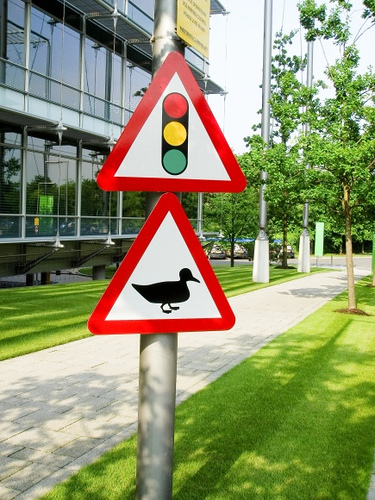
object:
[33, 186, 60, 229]
reflection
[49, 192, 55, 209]
grass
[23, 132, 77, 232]
window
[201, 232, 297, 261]
cars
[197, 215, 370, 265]
lot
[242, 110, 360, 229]
tree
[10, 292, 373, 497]
shadows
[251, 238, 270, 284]
cement base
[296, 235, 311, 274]
cement base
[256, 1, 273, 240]
light post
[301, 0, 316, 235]
light post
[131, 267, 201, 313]
silhouette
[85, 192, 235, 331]
triangle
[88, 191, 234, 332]
sign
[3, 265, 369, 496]
sidewalk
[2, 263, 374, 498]
lawn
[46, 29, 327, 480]
signs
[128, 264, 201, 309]
duck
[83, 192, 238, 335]
duck sign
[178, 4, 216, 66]
sign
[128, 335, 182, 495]
pole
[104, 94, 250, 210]
sign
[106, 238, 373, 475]
ground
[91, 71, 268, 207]
sign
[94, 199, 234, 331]
sign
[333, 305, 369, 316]
mulch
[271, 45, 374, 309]
tree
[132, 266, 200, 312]
black duck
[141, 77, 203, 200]
traffic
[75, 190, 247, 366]
sign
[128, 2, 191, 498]
pole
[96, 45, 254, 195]
sign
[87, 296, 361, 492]
grass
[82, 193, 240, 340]
sign